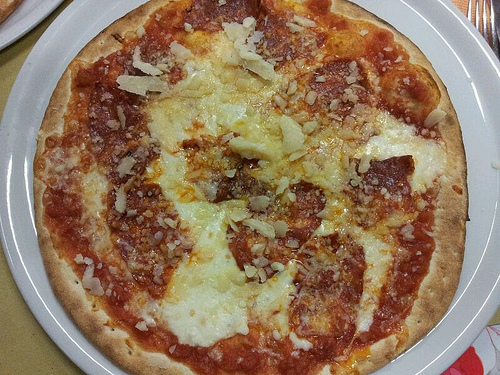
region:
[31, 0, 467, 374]
a small pizza margherita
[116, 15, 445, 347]
fresh grated parmesan or romano cheese unmelted on top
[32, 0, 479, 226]
edges, & probably bottom, of crust is lightly burnt across top down to mid-side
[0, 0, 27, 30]
another pizza in the far left top corner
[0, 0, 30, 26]
only a smidgen of crust visible of second pizza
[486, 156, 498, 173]
one piece of grated parmesan to mid-right corner of plate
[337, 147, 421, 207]
possibly a piece of prosciutto invading the margherita pizza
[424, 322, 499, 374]
floral napkin, with red poppy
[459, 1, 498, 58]
four fork tines, upper right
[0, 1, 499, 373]
tablecloth is light mustard yellow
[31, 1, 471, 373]
plain cheese pizza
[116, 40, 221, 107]
cheese sprinkles on top of pizza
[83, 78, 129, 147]
red sauce on pizza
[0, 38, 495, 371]
round white plate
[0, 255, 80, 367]
corner of tan tablecloth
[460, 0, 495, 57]
four prongs of silver fork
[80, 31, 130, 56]
brown pizza crust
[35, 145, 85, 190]
melted cheese on top of red sauce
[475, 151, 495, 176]
cheese crumb on white plate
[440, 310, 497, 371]
red and white floral image on tablecloth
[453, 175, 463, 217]
edge of a pizza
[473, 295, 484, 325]
edge of a plate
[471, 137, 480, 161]
inside of a plate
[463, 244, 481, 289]
a large white plate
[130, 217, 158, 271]
red meat on a pizza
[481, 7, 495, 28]
section of a fork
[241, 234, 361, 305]
white part of a pizza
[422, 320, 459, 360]
a large white plate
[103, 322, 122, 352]
edge of the food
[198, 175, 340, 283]
tasty food on the plate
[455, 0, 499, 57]
Four silver tines of fork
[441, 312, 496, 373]
White napkin with orange decoration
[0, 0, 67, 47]
Partial plate in upper left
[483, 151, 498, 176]
Small piece of cheese on plate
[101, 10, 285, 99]
Shreds of unmelted cheese on upper left of pizza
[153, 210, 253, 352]
Large glob of melted cheese on bottom left of pizza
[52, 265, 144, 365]
Four holes in crust at bottom left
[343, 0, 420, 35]
Darker area of crust on upper right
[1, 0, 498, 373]
Large white round plate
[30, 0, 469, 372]
Delicious round pizza ready to eat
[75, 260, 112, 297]
a delicious pizza topping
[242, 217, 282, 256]
a delicious pizza topping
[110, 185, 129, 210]
a delicious pizza topping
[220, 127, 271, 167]
a delicious pizza topping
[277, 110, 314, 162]
a delicious pizza topping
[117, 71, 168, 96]
a delicious pizza topping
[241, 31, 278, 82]
a delicious pizza topping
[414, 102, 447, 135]
a delicious pizza topping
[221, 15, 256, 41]
a delicious pizza topping